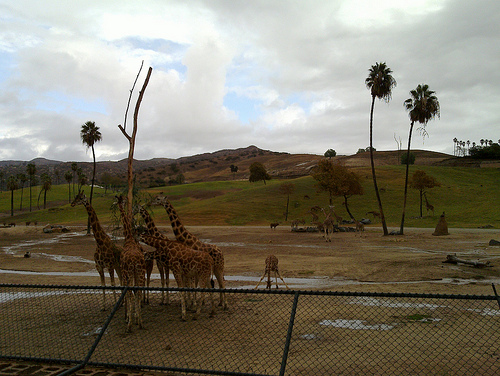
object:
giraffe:
[130, 199, 174, 307]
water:
[293, 333, 316, 341]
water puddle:
[319, 318, 399, 332]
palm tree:
[24, 160, 37, 214]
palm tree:
[33, 172, 53, 211]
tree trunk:
[368, 99, 395, 238]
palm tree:
[399, 83, 441, 235]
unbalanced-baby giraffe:
[251, 254, 290, 290]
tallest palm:
[364, 59, 396, 238]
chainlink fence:
[0, 282, 499, 376]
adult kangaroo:
[320, 208, 336, 243]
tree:
[118, 60, 156, 233]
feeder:
[119, 125, 137, 235]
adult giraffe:
[420, 188, 436, 217]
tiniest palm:
[285, 179, 292, 222]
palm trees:
[452, 137, 457, 156]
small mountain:
[0, 140, 500, 231]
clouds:
[0, 0, 497, 162]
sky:
[0, 0, 499, 164]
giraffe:
[320, 203, 338, 243]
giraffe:
[350, 218, 364, 239]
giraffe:
[69, 189, 125, 312]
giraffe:
[146, 191, 226, 317]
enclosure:
[0, 219, 500, 375]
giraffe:
[113, 193, 148, 335]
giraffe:
[135, 220, 216, 322]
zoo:
[0, 139, 499, 375]